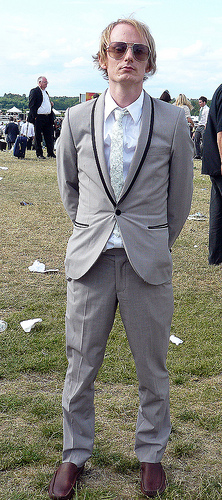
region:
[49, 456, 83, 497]
Man's blue shoe on the grass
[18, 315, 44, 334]
White napkin on the grass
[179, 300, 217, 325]
Green grass on the ground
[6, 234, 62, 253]
Clump of brown grass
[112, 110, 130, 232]
White tie on a man's shirt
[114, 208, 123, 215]
Black button on a jacket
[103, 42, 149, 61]
Sunglasses on a man's face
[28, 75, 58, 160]
Man in black suit on the grass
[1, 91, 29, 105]
Green trees in the background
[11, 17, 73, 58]
Clouds in a blue sky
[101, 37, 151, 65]
a pair of oversized sunglasses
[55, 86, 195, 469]
a light tan two piece suit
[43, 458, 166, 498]
dark brown loafers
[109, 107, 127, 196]
a spotted white and green tie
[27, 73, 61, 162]
a man wearing a black suit in the distance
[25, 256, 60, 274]
a piece of litter on the ground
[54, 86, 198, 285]
a small jacket stretched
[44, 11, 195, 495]
a man posing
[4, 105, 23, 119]
a white tent in the background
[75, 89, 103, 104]
a red billboard in the distance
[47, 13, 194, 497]
The man is wearing a gray suit.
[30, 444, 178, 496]
The man is wearing brown loafers.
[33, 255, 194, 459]
The man is wearing gray pants.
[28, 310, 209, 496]
The man is standing on grass.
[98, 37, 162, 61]
The man is wearing sunglasses.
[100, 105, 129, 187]
The man is wearing a tie.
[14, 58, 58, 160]
The man in the background is wearing a suit.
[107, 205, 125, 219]
A button on the jacket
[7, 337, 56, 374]
The grass is green.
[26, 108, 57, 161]
The man is wearing pants.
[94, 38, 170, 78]
man wearing sunglasses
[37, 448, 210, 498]
shoes of the man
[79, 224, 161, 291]
the midsection of hte pants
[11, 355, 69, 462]
the green grass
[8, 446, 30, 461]
slightly burned grass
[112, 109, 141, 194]
man's tie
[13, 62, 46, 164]
group of people in the back ground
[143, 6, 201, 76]
the partly cloudy sky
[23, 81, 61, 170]
man in black suit in back ground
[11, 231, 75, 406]
garbage on floor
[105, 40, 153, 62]
the sunglasses on the mans face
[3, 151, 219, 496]
the grass on the ground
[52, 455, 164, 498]
the loafers the man is wearing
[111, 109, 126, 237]
the pale tie the man is wearing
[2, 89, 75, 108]
some trees in the background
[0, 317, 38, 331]
some trash on the ground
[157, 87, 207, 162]
some people standing around and talking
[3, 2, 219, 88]
the blue sky above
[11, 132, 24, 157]
a suitcase sitting on the ground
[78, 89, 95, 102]
a billboard by the trees